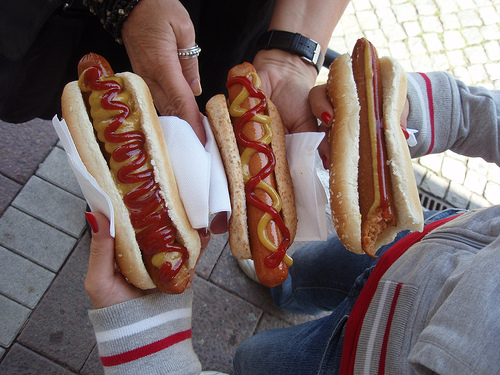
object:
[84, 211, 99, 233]
nail polish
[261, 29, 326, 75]
watchband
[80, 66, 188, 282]
mustard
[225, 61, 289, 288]
hot dog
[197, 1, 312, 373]
middle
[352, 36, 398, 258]
hot dog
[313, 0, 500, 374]
right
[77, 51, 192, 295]
hot dog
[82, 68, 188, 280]
ketchup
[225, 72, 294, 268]
ketchup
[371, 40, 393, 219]
ketchup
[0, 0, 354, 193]
person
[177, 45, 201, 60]
ring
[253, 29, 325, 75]
watch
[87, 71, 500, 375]
sweater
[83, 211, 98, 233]
thumb nail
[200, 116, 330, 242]
napkin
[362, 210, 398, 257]
bite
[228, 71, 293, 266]
mustard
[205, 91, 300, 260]
bun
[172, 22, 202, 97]
thumb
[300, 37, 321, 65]
silver buckle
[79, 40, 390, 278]
toppings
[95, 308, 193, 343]
white stripe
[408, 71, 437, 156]
stripes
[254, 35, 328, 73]
wrist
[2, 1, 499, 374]
ground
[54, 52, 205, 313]
held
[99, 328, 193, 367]
red stripe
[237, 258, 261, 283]
sneaker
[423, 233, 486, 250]
zipper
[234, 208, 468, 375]
jeans